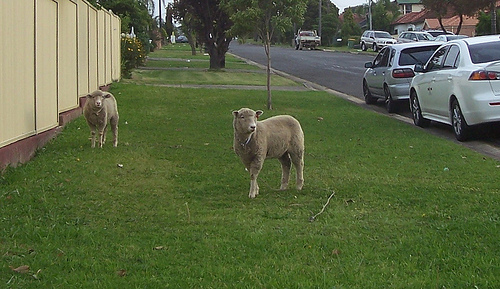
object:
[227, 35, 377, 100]
road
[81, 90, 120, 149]
sheep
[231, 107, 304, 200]
sheep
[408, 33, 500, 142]
car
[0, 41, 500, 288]
grass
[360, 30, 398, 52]
cars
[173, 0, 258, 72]
trees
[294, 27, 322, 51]
truck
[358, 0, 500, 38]
houses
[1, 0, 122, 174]
fence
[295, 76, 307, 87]
curb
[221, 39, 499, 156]
street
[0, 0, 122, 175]
wall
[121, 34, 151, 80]
bush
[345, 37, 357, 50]
trash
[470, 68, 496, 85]
lights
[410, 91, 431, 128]
tire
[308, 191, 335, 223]
stick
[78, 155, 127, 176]
leaves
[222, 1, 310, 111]
tree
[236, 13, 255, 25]
leaves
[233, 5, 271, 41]
branches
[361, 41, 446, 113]
car